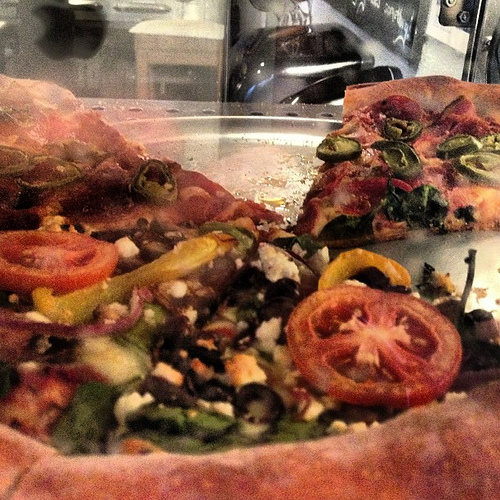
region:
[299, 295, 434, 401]
The vegetable is a tomato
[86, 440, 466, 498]
The crust is the color brown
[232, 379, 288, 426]
The vegetable is the color black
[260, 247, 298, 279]
The cheese is the color white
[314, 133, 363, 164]
The jalapeno is the color green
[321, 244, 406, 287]
The vegetable is the color yellow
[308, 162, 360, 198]
The pepperoni the color red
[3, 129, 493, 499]
A half of a pizza on the tray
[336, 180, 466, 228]
The green vegetable is basil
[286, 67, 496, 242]
a piece of pizza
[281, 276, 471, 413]
a slice of a tomato on a pizza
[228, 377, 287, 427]
an olive slice on a pizza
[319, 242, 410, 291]
a yellow pepper on a pizza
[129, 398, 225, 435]
a green pepper on a pizza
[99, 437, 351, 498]
a crust of a pizza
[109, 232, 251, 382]
the topping of a pizza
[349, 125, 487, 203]
the topping of a pizza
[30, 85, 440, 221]
a pizza on a pizza pan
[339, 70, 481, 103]
the crust of a pizza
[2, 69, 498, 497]
this fast food establishment sells pizza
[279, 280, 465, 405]
there are tomatoes on this pizza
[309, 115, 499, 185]
there are hot green chilis on this pizza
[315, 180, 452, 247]
there is spinach on this pizza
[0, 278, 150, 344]
there is red onion on this pizza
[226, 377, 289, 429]
there are olives on this pizza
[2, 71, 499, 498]
two slices of this pizza have been sold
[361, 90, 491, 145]
there is some kind of meat on this pizza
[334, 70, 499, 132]
this looks like a thin crust, not a pan crust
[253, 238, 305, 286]
there is feta cheese on this pizza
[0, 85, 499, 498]
Four slices of pizza are on the plate.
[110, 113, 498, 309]
The tray is silver.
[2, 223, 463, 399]
Two slices of tomato on pizza.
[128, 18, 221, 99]
White sink on leg.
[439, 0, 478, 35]
Two hexagonal nuts on black plate.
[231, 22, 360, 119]
Silver metal is shiny.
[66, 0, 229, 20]
Oven door with two handles.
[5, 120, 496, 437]
Pizza slices with black olives on them.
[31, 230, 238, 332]
Green pepper next to tomato.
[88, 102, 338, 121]
Seven round spots on silver surface.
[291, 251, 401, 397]
Tomato on pizza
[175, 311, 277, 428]
Olives on pizza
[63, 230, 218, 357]
peppers on a pizza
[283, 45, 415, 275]
Slice of vegetable pizza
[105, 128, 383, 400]
Pizza on a pizza pan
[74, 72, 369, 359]
Pizza in a window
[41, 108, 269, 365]
Vegetable on a pizza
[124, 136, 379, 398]
Vegetable pizza pie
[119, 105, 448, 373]
Pizza on a silver pan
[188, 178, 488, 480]
Pizza with tomatos on it